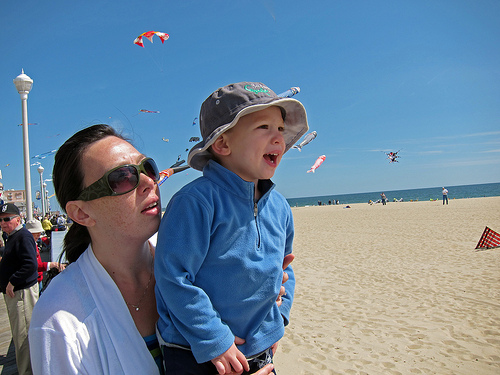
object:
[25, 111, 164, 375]
woman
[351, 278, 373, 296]
beach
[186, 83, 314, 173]
hat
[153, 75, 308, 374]
boy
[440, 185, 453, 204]
man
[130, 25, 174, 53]
kite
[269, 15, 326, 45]
sky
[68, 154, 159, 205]
sunglasses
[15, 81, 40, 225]
post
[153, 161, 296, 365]
sweater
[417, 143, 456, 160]
clouds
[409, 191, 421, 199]
ocean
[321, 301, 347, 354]
sand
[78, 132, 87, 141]
hair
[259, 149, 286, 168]
mouth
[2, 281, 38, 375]
pants